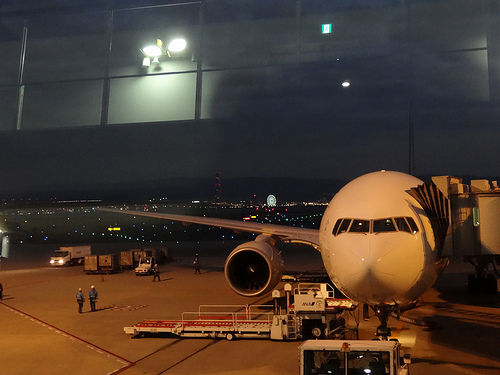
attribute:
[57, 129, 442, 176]
sky — overcast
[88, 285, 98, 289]
helmet — white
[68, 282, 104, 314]
men — standing, together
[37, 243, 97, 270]
truck — white, in motion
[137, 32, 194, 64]
headlights — on